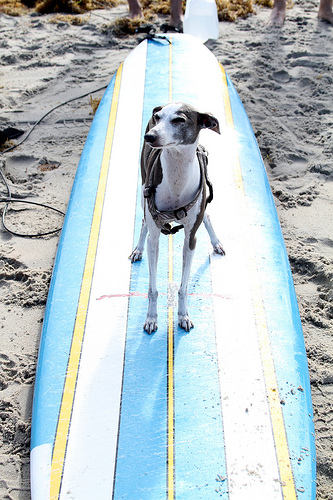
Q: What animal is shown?
A: Dog.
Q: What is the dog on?
A: Surfboard.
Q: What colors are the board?
A: Blue, white, yellow.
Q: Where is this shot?
A: Beach.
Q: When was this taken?
A: Daytime.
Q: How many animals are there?
A: 1.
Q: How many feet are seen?
A: 4.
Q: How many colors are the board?
A: 3.